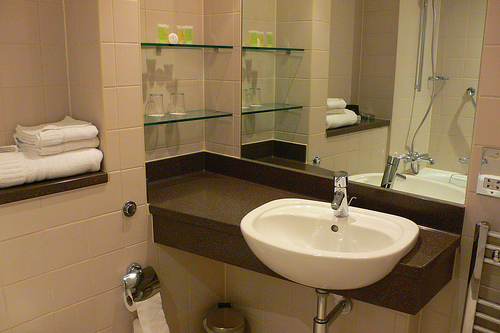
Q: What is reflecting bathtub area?
A: Mirror.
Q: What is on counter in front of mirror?
A: Sink.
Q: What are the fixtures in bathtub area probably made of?
A: Stainless steel.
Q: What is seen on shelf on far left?
A: Towels.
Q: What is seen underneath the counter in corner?
A: Trash can.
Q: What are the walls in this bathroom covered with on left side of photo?
A: Tiles.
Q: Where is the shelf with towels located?
A: Next to bathtub.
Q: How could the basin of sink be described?
A: Ovate.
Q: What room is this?
A: A bathroom.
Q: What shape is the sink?
A: An oval.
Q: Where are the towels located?
A: The shelf.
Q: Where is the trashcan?
A: Under the sink.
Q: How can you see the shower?
A: The mirror.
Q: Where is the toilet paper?
A: Hanging on the wall.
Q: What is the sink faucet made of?
A: Metal.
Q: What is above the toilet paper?
A: Door stop.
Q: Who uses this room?
A: People.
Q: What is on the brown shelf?
A: Towels.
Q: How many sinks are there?
A: One.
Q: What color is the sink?
A: White.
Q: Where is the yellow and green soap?
A: On glass shelf.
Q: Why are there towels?
A: To dry your hands.